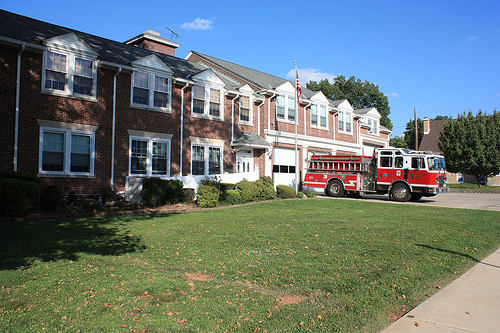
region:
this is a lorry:
[309, 145, 424, 191]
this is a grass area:
[281, 191, 380, 273]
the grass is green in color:
[348, 217, 403, 266]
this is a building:
[58, 100, 238, 169]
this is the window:
[45, 127, 94, 165]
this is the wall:
[95, 103, 127, 156]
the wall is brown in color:
[119, 98, 129, 119]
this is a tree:
[463, 116, 496, 156]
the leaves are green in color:
[468, 123, 484, 158]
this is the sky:
[398, 73, 457, 90]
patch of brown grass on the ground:
[179, 262, 219, 297]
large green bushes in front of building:
[143, 176, 276, 206]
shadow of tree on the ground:
[3, 213, 160, 276]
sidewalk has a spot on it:
[442, 248, 493, 331]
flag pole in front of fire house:
[290, 57, 305, 196]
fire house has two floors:
[117, 52, 274, 209]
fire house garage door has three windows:
[271, 139, 309, 194]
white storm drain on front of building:
[110, 63, 121, 195]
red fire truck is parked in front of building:
[302, 144, 462, 212]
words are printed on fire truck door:
[407, 152, 427, 189]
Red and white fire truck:
[291, 129, 453, 222]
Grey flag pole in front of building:
[285, 54, 317, 214]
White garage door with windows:
[268, 141, 315, 205]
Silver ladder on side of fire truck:
[303, 157, 375, 176]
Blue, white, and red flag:
[288, 68, 318, 108]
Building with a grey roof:
[33, 29, 378, 151]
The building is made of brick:
[26, 50, 386, 190]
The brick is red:
[35, 58, 398, 195]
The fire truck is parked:
[296, 141, 450, 211]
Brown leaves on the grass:
[7, 208, 481, 329]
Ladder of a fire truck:
[307, 157, 368, 177]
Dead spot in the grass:
[276, 286, 311, 308]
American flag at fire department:
[293, 63, 307, 111]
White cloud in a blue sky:
[180, 18, 227, 35]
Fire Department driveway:
[315, 183, 498, 219]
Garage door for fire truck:
[267, 138, 306, 204]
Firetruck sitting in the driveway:
[300, 146, 453, 209]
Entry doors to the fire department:
[232, 141, 258, 191]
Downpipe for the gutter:
[107, 58, 127, 190]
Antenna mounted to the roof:
[162, 23, 184, 46]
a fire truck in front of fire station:
[0, 0, 460, 211]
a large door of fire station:
[260, 122, 305, 197]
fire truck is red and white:
[288, 135, 454, 210]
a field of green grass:
[18, 184, 495, 329]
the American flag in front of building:
[287, 56, 312, 196]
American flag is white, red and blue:
[286, 60, 311, 107]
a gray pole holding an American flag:
[288, 62, 310, 197]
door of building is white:
[263, 133, 306, 190]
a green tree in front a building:
[435, 105, 499, 195]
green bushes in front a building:
[131, 172, 304, 212]